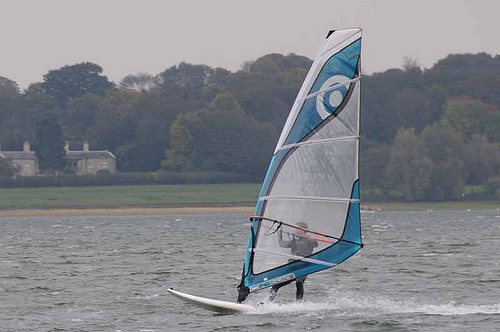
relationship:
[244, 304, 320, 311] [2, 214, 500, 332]
white foamy water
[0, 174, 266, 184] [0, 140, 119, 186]
hedges near house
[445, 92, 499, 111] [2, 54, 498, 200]
red over trees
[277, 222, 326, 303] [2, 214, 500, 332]
man in water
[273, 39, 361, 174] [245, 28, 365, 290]
blue on sail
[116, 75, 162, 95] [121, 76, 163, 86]
tree no leaves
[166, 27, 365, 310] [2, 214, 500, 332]
equipment out of water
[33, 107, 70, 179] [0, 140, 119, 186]
tree before house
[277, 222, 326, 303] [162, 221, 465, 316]
man wind surfing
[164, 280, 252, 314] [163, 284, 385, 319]
front of surfboard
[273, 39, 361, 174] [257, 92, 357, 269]
blue and white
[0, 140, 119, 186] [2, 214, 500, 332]
house by water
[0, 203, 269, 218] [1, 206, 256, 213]
beach of sand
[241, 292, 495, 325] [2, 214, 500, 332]
wake in water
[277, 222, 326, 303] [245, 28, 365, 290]
surfer holding sail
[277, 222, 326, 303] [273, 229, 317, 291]
surfer wears wetsuit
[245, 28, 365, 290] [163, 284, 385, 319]
sail on board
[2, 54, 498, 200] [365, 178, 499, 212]
trees along shore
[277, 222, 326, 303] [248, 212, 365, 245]
surfer holds stick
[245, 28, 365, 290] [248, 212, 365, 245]
sail with stick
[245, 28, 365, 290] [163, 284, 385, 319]
sail attached to board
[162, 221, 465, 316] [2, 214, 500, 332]
surf on lake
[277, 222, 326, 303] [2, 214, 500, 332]
man on calm lake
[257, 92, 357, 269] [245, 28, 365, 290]
white on sail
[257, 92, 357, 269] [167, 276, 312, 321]
white surf board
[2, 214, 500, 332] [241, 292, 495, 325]
lake has wake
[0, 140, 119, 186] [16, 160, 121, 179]
house of stone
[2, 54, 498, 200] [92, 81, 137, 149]
trees turn color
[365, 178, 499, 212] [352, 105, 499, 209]
shore has trees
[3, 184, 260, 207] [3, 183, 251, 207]
trimmed green grass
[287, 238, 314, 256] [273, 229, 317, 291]
black wet wetsuit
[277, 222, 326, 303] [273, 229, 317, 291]
man in wetsuit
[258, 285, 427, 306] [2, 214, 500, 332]
spray of water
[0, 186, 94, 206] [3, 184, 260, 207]
green manicured lawn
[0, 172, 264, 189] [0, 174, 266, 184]
row of bushes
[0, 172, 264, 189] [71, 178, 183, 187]
row of green